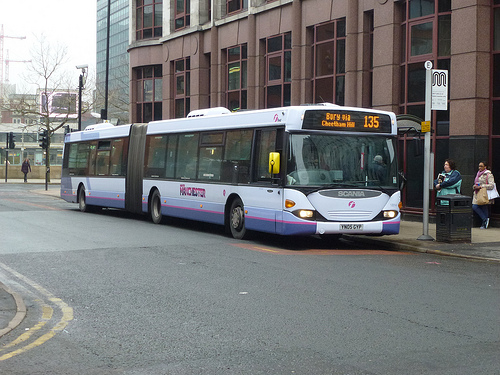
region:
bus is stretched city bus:
[58, 99, 400, 243]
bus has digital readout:
[299, 108, 393, 135]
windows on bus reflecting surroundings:
[61, 131, 396, 188]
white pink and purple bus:
[61, 105, 400, 236]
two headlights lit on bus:
[283, 198, 403, 221]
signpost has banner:
[415, 58, 447, 243]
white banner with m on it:
[427, 67, 447, 112]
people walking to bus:
[420, 156, 496, 232]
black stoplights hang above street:
[5, 128, 50, 149]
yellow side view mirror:
[267, 150, 281, 175]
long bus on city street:
[52, 90, 407, 243]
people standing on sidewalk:
[430, 145, 490, 227]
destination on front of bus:
[315, 105, 355, 130]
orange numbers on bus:
[357, 105, 382, 135]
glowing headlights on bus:
[291, 200, 401, 226]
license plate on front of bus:
[330, 216, 371, 236]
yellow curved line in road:
[27, 290, 82, 341]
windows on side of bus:
[142, 127, 219, 182]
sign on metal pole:
[421, 60, 456, 117]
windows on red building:
[216, 15, 410, 95]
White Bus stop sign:
[423, 57, 450, 111]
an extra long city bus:
[61, 102, 403, 240]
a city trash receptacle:
[434, 192, 472, 242]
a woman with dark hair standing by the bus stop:
[436, 157, 462, 208]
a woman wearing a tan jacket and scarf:
[471, 160, 498, 227]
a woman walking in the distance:
[18, 157, 34, 182]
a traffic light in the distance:
[39, 127, 52, 192]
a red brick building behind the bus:
[130, 61, 491, 133]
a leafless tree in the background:
[14, 60, 77, 180]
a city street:
[1, 182, 498, 372]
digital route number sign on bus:
[319, 112, 385, 132]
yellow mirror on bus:
[268, 151, 278, 176]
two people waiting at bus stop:
[437, 160, 499, 232]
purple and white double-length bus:
[60, 103, 402, 248]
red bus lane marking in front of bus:
[236, 242, 422, 260]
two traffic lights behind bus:
[4, 127, 51, 192]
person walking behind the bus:
[21, 159, 31, 179]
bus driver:
[370, 155, 384, 180]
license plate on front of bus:
[341, 223, 363, 233]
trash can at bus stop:
[435, 192, 470, 242]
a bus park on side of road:
[51, 100, 416, 245]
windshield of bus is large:
[296, 129, 403, 194]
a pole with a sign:
[418, 49, 454, 165]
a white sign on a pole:
[426, 64, 454, 113]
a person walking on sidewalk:
[18, 147, 38, 187]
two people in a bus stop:
[431, 146, 498, 239]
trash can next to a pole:
[431, 190, 478, 250]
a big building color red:
[130, 2, 499, 117]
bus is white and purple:
[50, 96, 417, 252]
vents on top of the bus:
[170, 96, 235, 120]